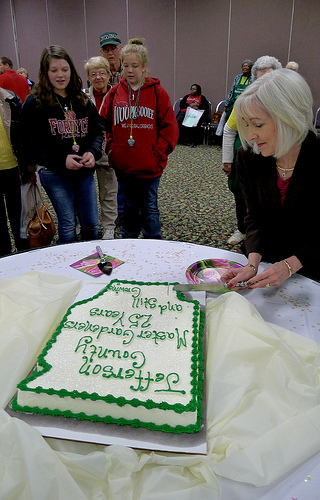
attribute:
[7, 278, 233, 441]
cake — green and white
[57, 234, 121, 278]
napkin — pink , gray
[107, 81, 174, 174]
shirt — red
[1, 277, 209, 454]
cake — green, white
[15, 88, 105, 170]
shirt — black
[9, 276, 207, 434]
frosting — green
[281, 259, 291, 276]
bracelet — gold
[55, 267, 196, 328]
cake — green , piping , decorated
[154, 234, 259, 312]
plate — paper 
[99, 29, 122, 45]
hat — green 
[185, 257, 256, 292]
plate — colorful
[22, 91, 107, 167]
sweatshirt — black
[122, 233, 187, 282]
cloth —  White 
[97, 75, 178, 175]
sweatshirt — red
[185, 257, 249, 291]
plate — paper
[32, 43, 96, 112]
hair — brown 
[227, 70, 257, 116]
shirt — green